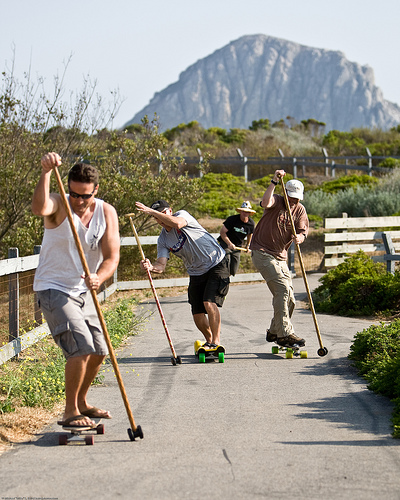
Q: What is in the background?
A: Mountain.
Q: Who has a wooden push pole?
A: All men with skateboards.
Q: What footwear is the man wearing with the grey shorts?
A: Flip flops.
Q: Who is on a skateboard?
A: The man.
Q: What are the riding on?
A: Asphalt.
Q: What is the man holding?
A: A pole.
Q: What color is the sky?
A: Blue gray.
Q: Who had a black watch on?
A: The man.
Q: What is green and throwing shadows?
A: Shrubs.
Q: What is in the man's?
A: Large sticks.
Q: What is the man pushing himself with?
A: Skateboard.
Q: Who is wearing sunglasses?
A: The man.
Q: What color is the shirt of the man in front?
A: White.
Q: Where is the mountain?
A: In the back.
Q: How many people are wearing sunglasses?
A: One.